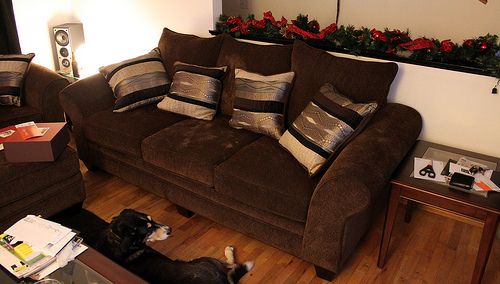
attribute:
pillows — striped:
[89, 31, 372, 203]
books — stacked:
[9, 199, 70, 256]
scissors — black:
[414, 152, 466, 211]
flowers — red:
[322, 43, 494, 85]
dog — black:
[129, 206, 261, 276]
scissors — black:
[416, 140, 448, 189]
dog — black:
[144, 191, 217, 275]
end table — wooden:
[371, 136, 499, 278]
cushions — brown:
[86, 99, 320, 229]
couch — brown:
[55, 23, 422, 276]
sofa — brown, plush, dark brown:
[54, 26, 424, 276]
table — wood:
[362, 135, 498, 282]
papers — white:
[410, 154, 499, 196]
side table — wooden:
[368, 137, 496, 282]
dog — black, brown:
[97, 207, 257, 282]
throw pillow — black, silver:
[151, 54, 229, 126]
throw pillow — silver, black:
[225, 59, 299, 146]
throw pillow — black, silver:
[266, 82, 383, 179]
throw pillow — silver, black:
[0, 47, 43, 109]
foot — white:
[220, 243, 239, 272]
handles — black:
[416, 163, 438, 181]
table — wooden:
[374, 137, 484, 282]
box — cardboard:
[0, 116, 74, 165]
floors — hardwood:
[63, 124, 484, 282]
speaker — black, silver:
[43, 7, 90, 87]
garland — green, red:
[210, 10, 483, 75]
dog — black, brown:
[89, 194, 218, 281]